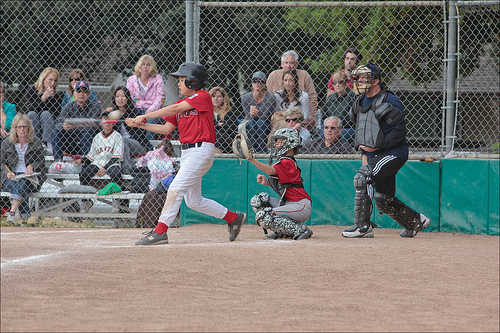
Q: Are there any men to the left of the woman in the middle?
A: Yes, there is a man to the left of the woman.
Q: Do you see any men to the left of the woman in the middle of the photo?
A: Yes, there is a man to the left of the woman.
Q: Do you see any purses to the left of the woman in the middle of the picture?
A: No, there is a man to the left of the woman.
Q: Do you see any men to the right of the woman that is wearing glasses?
A: Yes, there is a man to the right of the woman.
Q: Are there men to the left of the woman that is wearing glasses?
A: No, the man is to the right of the woman.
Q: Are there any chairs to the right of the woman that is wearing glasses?
A: No, there is a man to the right of the woman.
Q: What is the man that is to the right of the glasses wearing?
A: The man is wearing a cap.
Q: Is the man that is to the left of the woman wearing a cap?
A: Yes, the man is wearing a cap.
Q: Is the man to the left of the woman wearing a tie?
A: No, the man is wearing a cap.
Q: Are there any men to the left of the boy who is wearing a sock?
A: Yes, there is a man to the left of the boy.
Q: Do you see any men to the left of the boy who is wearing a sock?
A: Yes, there is a man to the left of the boy.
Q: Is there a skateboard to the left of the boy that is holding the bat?
A: No, there is a man to the left of the boy.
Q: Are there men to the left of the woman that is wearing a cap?
A: Yes, there is a man to the left of the woman.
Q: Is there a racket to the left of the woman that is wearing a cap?
A: No, there is a man to the left of the woman.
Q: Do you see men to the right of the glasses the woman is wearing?
A: Yes, there is a man to the right of the glasses.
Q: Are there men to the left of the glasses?
A: No, the man is to the right of the glasses.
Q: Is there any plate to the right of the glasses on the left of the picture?
A: No, there is a man to the right of the glasses.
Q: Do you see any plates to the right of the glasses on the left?
A: No, there is a man to the right of the glasses.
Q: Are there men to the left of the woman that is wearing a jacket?
A: Yes, there is a man to the left of the woman.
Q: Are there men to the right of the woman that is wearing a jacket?
A: No, the man is to the left of the woman.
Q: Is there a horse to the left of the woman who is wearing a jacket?
A: No, there is a man to the left of the woman.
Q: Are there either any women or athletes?
A: Yes, there is a woman.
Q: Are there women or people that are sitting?
A: Yes, the woman is sitting.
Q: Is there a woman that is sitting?
A: Yes, there is a woman that is sitting.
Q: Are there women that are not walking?
A: Yes, there is a woman that is sitting.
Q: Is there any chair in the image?
A: No, there are no chairs.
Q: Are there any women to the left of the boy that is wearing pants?
A: Yes, there is a woman to the left of the boy.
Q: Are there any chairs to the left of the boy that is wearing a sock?
A: No, there is a woman to the left of the boy.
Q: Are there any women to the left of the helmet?
A: Yes, there is a woman to the left of the helmet.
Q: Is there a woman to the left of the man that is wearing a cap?
A: Yes, there is a woman to the left of the man.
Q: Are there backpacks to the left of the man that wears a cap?
A: No, there is a woman to the left of the man.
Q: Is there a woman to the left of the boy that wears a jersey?
A: Yes, there is a woman to the left of the boy.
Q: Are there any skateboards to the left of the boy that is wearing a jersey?
A: No, there is a woman to the left of the boy.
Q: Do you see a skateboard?
A: No, there are no skateboards.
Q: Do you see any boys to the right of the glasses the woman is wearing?
A: Yes, there is a boy to the right of the glasses.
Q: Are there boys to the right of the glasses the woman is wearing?
A: Yes, there is a boy to the right of the glasses.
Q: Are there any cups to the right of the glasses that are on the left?
A: No, there is a boy to the right of the glasses.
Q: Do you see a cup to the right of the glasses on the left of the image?
A: No, there is a boy to the right of the glasses.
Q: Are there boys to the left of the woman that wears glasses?
A: No, the boy is to the right of the woman.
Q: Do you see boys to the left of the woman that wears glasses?
A: No, the boy is to the right of the woman.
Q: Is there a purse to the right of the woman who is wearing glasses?
A: No, there is a boy to the right of the woman.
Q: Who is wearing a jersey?
A: The boy is wearing a jersey.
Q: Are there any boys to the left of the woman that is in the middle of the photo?
A: Yes, there is a boy to the left of the woman.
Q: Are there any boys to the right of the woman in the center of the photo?
A: No, the boy is to the left of the woman.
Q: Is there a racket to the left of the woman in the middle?
A: No, there is a boy to the left of the woman.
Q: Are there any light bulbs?
A: No, there are no light bulbs.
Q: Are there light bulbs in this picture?
A: No, there are no light bulbs.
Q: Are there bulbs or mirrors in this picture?
A: No, there are no bulbs or mirrors.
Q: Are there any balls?
A: No, there are no balls.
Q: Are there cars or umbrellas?
A: No, there are no cars or umbrellas.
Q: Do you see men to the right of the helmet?
A: Yes, there is a man to the right of the helmet.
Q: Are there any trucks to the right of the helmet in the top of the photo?
A: No, there is a man to the right of the helmet.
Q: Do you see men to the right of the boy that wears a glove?
A: Yes, there is a man to the right of the boy.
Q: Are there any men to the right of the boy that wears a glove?
A: Yes, there is a man to the right of the boy.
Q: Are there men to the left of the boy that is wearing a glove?
A: No, the man is to the right of the boy.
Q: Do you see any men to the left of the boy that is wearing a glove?
A: No, the man is to the right of the boy.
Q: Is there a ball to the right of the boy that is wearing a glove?
A: No, there is a man to the right of the boy.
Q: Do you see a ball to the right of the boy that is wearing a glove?
A: No, there is a man to the right of the boy.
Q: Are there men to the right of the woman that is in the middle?
A: Yes, there is a man to the right of the woman.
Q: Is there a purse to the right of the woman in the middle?
A: No, there is a man to the right of the woman.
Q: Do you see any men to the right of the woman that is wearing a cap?
A: Yes, there is a man to the right of the woman.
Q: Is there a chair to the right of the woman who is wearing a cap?
A: No, there is a man to the right of the woman.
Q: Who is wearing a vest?
A: The man is wearing a vest.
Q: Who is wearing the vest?
A: The man is wearing a vest.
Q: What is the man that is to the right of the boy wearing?
A: The man is wearing a vest.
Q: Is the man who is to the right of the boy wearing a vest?
A: Yes, the man is wearing a vest.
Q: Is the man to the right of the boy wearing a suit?
A: No, the man is wearing a vest.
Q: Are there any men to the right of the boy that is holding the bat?
A: Yes, there is a man to the right of the boy.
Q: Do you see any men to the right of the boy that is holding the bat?
A: Yes, there is a man to the right of the boy.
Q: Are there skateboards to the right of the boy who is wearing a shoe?
A: No, there is a man to the right of the boy.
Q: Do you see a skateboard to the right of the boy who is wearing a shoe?
A: No, there is a man to the right of the boy.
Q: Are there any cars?
A: No, there are no cars.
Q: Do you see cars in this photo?
A: No, there are no cars.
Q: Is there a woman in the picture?
A: Yes, there is a woman.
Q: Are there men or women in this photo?
A: Yes, there is a woman.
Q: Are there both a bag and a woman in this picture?
A: No, there is a woman but no bags.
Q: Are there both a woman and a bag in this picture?
A: No, there is a woman but no bags.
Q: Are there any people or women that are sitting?
A: Yes, the woman is sitting.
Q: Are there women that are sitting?
A: Yes, there is a woman that is sitting.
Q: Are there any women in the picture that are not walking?
A: Yes, there is a woman that is sitting.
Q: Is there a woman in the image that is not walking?
A: Yes, there is a woman that is sitting.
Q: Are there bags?
A: No, there are no bags.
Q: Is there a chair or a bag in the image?
A: No, there are no bags or chairs.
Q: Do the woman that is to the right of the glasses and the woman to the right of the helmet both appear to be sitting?
A: Yes, both the woman and the woman are sitting.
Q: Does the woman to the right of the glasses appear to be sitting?
A: Yes, the woman is sitting.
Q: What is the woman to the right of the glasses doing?
A: The woman is sitting.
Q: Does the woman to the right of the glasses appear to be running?
A: No, the woman is sitting.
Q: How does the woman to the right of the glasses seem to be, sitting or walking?
A: The woman is sitting.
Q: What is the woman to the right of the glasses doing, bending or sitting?
A: The woman is sitting.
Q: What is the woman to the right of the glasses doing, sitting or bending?
A: The woman is sitting.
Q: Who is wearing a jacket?
A: The woman is wearing a jacket.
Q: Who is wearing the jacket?
A: The woman is wearing a jacket.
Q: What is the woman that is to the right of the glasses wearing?
A: The woman is wearing a jacket.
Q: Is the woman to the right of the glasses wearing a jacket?
A: Yes, the woman is wearing a jacket.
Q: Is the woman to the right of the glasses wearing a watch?
A: No, the woman is wearing a jacket.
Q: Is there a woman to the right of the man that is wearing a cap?
A: Yes, there is a woman to the right of the man.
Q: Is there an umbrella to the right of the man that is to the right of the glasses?
A: No, there is a woman to the right of the man.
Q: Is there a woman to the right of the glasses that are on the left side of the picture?
A: Yes, there is a woman to the right of the glasses.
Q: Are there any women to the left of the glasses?
A: No, the woman is to the right of the glasses.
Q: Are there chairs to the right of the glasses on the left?
A: No, there is a woman to the right of the glasses.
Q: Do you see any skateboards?
A: No, there are no skateboards.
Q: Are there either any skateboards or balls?
A: No, there are no skateboards or balls.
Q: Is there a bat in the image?
A: Yes, there is a bat.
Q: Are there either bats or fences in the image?
A: Yes, there is a bat.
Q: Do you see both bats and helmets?
A: Yes, there are both a bat and a helmet.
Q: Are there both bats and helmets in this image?
A: Yes, there are both a bat and a helmet.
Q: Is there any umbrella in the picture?
A: No, there are no umbrellas.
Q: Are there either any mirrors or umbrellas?
A: No, there are no umbrellas or mirrors.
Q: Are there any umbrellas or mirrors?
A: No, there are no umbrellas or mirrors.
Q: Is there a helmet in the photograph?
A: Yes, there is a helmet.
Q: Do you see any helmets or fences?
A: Yes, there is a helmet.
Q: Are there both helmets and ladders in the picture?
A: No, there is a helmet but no ladders.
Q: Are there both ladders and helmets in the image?
A: No, there is a helmet but no ladders.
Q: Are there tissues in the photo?
A: No, there are no tissues.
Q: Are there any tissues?
A: No, there are no tissues.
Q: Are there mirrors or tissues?
A: No, there are no tissues or mirrors.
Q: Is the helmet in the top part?
A: Yes, the helmet is in the top of the image.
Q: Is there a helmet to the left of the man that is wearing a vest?
A: Yes, there is a helmet to the left of the man.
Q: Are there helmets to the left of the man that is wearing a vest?
A: Yes, there is a helmet to the left of the man.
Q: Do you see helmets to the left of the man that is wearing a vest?
A: Yes, there is a helmet to the left of the man.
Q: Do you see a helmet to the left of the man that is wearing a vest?
A: Yes, there is a helmet to the left of the man.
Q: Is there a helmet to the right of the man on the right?
A: No, the helmet is to the left of the man.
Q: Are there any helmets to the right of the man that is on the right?
A: No, the helmet is to the left of the man.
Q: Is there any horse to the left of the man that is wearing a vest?
A: No, there is a helmet to the left of the man.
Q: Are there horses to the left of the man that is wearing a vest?
A: No, there is a helmet to the left of the man.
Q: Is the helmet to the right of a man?
A: No, the helmet is to the left of a man.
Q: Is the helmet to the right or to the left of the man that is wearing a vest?
A: The helmet is to the left of the man.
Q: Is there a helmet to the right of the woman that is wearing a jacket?
A: Yes, there is a helmet to the right of the woman.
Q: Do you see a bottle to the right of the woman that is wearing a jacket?
A: No, there is a helmet to the right of the woman.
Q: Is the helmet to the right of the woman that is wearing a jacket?
A: Yes, the helmet is to the right of the woman.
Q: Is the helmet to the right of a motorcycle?
A: No, the helmet is to the right of the woman.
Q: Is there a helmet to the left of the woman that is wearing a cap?
A: Yes, there is a helmet to the left of the woman.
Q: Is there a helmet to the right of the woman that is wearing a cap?
A: No, the helmet is to the left of the woman.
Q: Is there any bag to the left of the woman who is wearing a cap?
A: No, there is a helmet to the left of the woman.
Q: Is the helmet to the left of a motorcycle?
A: No, the helmet is to the left of a woman.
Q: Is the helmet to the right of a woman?
A: No, the helmet is to the left of a woman.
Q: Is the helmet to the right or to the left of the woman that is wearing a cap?
A: The helmet is to the left of the woman.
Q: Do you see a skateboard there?
A: No, there are no skateboards.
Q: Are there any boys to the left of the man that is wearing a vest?
A: Yes, there is a boy to the left of the man.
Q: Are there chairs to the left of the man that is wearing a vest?
A: No, there is a boy to the left of the man.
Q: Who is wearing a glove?
A: The boy is wearing a glove.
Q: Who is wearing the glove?
A: The boy is wearing a glove.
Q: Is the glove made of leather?
A: Yes, the glove is made of leather.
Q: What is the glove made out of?
A: The glove is made of leather.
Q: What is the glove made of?
A: The glove is made of leather.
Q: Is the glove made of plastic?
A: No, the glove is made of leather.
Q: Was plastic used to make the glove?
A: No, the glove is made of leather.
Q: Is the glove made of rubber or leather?
A: The glove is made of leather.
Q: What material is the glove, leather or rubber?
A: The glove is made of leather.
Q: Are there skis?
A: No, there are no skis.